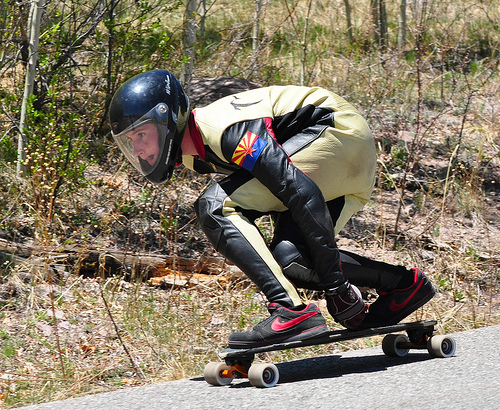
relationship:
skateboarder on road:
[88, 56, 442, 350] [336, 356, 496, 409]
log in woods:
[18, 241, 175, 282] [1, 9, 102, 259]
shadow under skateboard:
[281, 350, 415, 382] [204, 323, 464, 384]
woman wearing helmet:
[88, 56, 442, 350] [104, 71, 188, 184]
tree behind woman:
[170, 4, 226, 79] [88, 56, 442, 350]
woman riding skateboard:
[88, 56, 442, 350] [204, 323, 464, 384]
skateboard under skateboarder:
[204, 323, 464, 384] [108, 69, 436, 350]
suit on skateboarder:
[196, 83, 390, 293] [108, 69, 436, 350]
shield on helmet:
[111, 115, 169, 171] [104, 71, 188, 184]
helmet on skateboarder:
[104, 71, 188, 184] [108, 69, 436, 350]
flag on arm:
[233, 125, 270, 172] [219, 115, 344, 280]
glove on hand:
[316, 286, 376, 328] [341, 294, 369, 314]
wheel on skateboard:
[381, 334, 413, 362] [204, 323, 464, 384]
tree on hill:
[170, 4, 226, 79] [308, 32, 486, 81]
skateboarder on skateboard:
[108, 69, 436, 350] [204, 323, 464, 384]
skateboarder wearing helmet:
[108, 69, 436, 350] [104, 71, 188, 184]